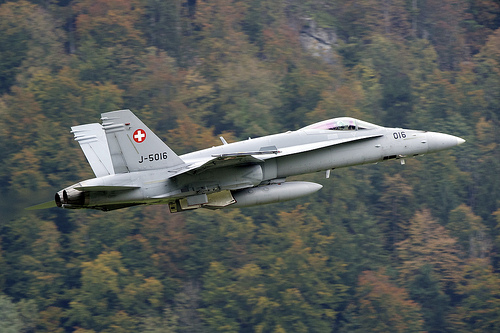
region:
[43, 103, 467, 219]
swiss military aircraft in flight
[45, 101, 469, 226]
military plane in flight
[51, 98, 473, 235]
gray jet plane facing right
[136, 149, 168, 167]
jet identification number on tail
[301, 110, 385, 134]
cockpit of jet aircraft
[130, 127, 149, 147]
red and white swiss logo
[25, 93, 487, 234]
this is a plane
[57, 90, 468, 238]
the plane is white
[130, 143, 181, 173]
numbers on the plane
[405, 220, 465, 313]
this is a tree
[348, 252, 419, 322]
this is a tree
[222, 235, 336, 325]
this is a tree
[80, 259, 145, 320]
this is a tree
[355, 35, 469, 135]
this is a tree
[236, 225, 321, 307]
this is a tree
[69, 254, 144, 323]
this is a tree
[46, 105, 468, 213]
jet plane in the air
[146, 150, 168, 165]
number on the tail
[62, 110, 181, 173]
tail of the jet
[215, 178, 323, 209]
missile under the jet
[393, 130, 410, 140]
number on the front of the jet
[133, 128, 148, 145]
emblem on the tail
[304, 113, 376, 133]
cockpit of the jet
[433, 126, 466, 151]
nose of the jet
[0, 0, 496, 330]
trees behind the jet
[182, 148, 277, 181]
wing of the jet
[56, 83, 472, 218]
white jet in air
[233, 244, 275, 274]
green and brown leaves on trees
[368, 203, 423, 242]
green and brown leaves on trees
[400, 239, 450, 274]
green and brown leaves on trees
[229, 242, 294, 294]
green and brown leaves on trees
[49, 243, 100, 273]
green and brown leaves on trees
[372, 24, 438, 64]
green and brown leaves on trees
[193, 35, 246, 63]
green and brown leaves on trees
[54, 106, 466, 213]
the airplane that is flying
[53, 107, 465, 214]
the airplane in mid air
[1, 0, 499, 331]
the trees beneath the airplane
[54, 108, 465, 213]
jet is flying in the air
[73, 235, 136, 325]
A tree in the woods.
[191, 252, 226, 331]
A tree in the woods.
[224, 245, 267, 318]
A tree in the woods.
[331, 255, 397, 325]
A tree in the woods.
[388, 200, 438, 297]
A tree in the woods.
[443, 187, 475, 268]
A tree in the woods.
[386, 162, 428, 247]
A tree in the woods.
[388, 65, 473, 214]
A tree in the woods.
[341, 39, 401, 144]
A tree in the woods.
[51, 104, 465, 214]
airplane flying in the sky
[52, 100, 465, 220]
grey metal fighter jet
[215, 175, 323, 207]
missile on bottom of airplane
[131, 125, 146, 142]
red circle with white cross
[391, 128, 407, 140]
numbers painted in black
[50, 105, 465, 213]
airplane flying next to forest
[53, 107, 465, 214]
airplane flying over forest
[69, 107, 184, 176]
two white back plane wings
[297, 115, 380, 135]
small shiny glass cockpit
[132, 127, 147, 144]
red and white symbol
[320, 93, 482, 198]
front of the plane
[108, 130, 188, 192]
number on the plane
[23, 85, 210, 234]
tail of the plane